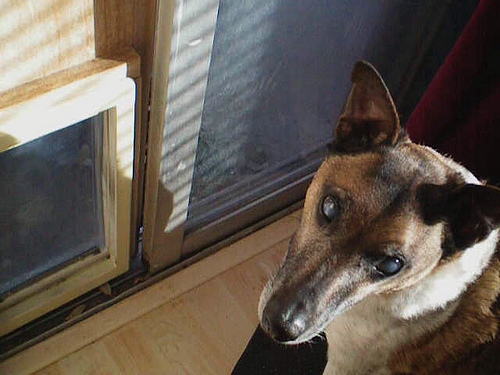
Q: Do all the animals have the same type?
A: Yes, all the animals are sheep.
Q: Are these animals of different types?
A: No, all the animals are sheep.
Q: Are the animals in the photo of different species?
A: No, all the animals are sheep.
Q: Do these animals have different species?
A: No, all the animals are sheep.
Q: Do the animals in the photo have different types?
A: No, all the animals are sheep.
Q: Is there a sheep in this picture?
A: Yes, there is a sheep.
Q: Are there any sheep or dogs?
A: Yes, there is a sheep.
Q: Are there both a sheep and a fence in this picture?
A: No, there is a sheep but no fences.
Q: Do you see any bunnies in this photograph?
A: No, there are no bunnies.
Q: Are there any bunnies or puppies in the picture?
A: No, there are no bunnies or puppies.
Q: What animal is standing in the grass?
A: The sheep is standing in the grass.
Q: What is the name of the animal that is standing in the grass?
A: The animal is a sheep.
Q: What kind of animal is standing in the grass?
A: The animal is a sheep.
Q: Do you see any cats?
A: No, there are no cats.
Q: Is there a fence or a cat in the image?
A: No, there are no cats or fences.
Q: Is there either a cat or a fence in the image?
A: No, there are no cats or fences.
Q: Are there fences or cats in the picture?
A: No, there are no cats or fences.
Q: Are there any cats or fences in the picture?
A: No, there are no cats or fences.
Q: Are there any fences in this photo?
A: No, there are no fences.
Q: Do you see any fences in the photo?
A: No, there are no fences.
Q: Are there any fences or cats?
A: No, there are no fences or cats.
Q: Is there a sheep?
A: Yes, there is a sheep.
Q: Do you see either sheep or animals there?
A: Yes, there is a sheep.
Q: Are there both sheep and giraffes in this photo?
A: No, there is a sheep but no giraffes.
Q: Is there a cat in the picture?
A: No, there are no cats.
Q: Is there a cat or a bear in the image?
A: No, there are no cats or bears.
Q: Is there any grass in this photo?
A: Yes, there is grass.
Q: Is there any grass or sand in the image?
A: Yes, there is grass.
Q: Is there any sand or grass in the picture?
A: Yes, there is grass.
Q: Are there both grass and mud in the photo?
A: No, there is grass but no mud.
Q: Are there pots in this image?
A: No, there are no pots.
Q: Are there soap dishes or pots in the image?
A: No, there are no pots or soap dishes.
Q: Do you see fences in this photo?
A: No, there are no fences.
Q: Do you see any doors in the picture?
A: Yes, there is a door.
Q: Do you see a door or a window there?
A: Yes, there is a door.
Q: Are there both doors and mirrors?
A: No, there is a door but no mirrors.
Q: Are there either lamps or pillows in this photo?
A: No, there are no lamps or pillows.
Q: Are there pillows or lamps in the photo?
A: No, there are no lamps or pillows.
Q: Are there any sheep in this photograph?
A: Yes, there is a sheep.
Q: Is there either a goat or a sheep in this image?
A: Yes, there is a sheep.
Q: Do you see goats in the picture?
A: No, there are no goats.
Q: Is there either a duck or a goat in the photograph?
A: No, there are no goats or ducks.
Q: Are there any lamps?
A: No, there are no lamps.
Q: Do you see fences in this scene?
A: No, there are no fences.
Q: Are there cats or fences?
A: No, there are no fences or cats.